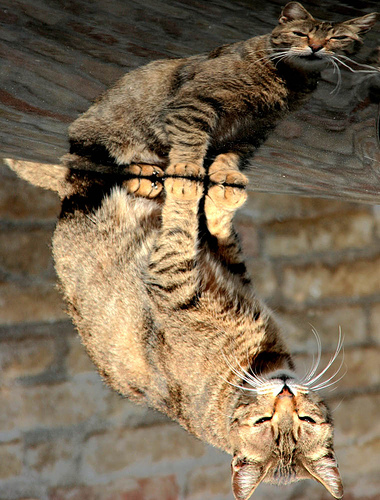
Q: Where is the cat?
A: By the water.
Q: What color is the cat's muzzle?
A: White.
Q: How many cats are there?
A: One.